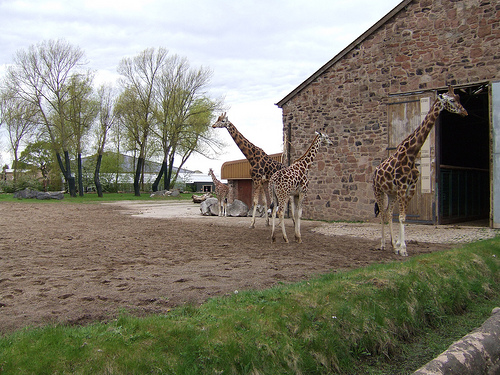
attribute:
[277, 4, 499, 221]
building — brown, open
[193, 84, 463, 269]
giraffes — yellow, tall, brown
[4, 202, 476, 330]
dirt — brown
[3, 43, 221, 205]
trees — green, thin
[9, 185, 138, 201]
grass — green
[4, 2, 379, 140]
sky — white